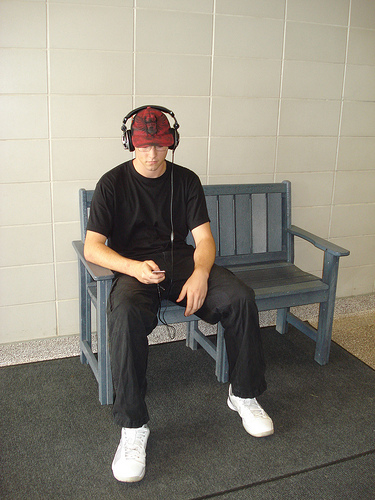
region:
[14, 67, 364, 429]
a man wearing on a bench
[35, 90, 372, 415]
a man sitting on a blue bench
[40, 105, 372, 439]
a man sitting on a wood bench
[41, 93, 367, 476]
a man sitting on a blue wood bench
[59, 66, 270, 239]
a man wearing headphones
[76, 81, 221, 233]
a man wearing large headphones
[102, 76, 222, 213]
a man wearing a hat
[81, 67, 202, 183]
a man wearing a red hat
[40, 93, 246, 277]
a man wearing a shirt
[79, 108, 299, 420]
a man wearing pants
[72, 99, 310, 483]
Man sitting on a wooden bench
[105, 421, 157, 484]
White tennis shoe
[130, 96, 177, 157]
Red baseball cap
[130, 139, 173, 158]
Man wearing glasses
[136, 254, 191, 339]
Man holding an ipod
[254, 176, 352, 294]
A gray wooden bench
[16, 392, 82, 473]
A gray carpet or rug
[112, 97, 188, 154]
Man wearing a headphone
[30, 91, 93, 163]
A white tile wall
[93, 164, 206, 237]
A black tee shirt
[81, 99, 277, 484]
A man listening to music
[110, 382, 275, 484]
A pair of white sneakers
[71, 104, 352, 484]
A man sitting on a bench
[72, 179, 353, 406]
A blue wooden bench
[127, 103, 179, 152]
A red colored hat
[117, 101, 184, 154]
Headphones on a man's head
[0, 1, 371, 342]
White tiles on the wall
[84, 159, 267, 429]
Black shirt and pants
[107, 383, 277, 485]
Two feet on the floor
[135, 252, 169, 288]
Cell phone in a hand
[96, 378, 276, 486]
Man is wearing shoes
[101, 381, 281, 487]
Man is wearing white shoes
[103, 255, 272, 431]
Man is wearing pants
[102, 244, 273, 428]
Man is wearing black pants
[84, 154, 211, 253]
Man is wearing a shirt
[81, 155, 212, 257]
Man is wearing a black shirt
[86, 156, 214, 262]
Man is wearing a t-shirt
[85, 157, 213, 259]
Man is wearing a black t-shirt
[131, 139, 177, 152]
Man is wearing glasses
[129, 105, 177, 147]
Man is wearing a hat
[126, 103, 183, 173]
the head of a man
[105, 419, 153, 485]
a white tennis shoe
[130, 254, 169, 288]
the hand of a man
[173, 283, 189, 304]
the thumb of a man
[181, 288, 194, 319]
the finger of a man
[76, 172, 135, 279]
the arm of a man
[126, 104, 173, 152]
a red baseball cap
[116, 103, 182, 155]
a pair of head phones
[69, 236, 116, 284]
a gray bench arm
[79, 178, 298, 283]
the back of a bench